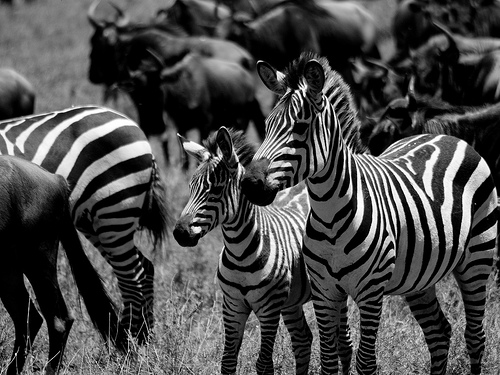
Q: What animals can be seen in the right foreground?
A: Zebras.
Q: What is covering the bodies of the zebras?
A: Stripes.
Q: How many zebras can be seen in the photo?
A: Three.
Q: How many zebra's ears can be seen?
A: Four.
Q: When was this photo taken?
A: Daytime.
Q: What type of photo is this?
A: Black and White.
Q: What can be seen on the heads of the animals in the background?
A: Horns.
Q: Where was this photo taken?
A: Africa.